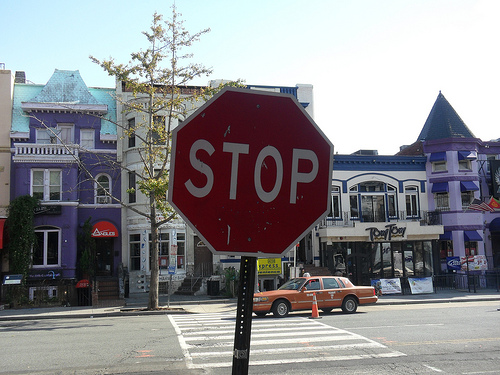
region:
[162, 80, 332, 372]
a red and white stop sign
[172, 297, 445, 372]
white lines forming a crosswalk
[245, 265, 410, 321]
orange taxi on street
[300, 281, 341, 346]
orange traffic cone on street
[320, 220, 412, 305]
store sign over first story of building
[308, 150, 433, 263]
white building with blue details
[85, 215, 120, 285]
red awning over entrance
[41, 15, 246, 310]
tree in front of buildings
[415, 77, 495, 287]
purple building with purple awnings over windows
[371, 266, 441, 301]
signs on the sidewalk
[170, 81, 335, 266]
A stop sign.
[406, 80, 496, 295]
The roof of purple building is shaped like a pyramid.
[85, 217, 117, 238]
A red business sign.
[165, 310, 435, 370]
A crosswalk.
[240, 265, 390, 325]
A traffic cone is next to a taxi.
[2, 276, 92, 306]
A metal fence.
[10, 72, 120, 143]
The roof is light blue.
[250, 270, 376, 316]
An orange taxi.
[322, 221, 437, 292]
The storefront of a business.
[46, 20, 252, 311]
A large tree with few leaves.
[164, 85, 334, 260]
red octagonal stop sign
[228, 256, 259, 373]
metal pole supporting stop sign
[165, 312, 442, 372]
painted crosswalk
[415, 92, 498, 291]
building with blue awnings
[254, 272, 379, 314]
orange taxicab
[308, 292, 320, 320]
orange safety cone in street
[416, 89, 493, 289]
building with conical roof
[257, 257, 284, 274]
yellow store awning that says "express"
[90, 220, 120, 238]
red store awning above door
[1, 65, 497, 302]
row of commercial establishments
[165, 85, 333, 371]
The red stop sign with white writing.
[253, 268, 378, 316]
The orange taxi cab.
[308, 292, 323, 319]
The orange and white construction cone.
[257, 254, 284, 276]
The yellow express sign.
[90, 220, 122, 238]
The red awning with white designs.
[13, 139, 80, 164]
The white top floor balcony.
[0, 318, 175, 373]
A grey road with shadows.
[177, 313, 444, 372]
The white road lines.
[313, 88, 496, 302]
The businesses in the area.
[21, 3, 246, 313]
The one tall tree.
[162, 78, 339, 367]
A RED AND WHITE STOP SIGN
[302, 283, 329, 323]
AN ORANGE TRAFFIC CONE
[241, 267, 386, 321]
AN ORANGE TAXI CAB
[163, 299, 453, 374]
WHITE CROSS WALK MARKINGS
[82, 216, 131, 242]
A RED AWNING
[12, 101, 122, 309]
A PURPLE AND WHITE BUILDING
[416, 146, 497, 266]
SIX WINDOWS WITH AWNINGS?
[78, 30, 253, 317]
A TREE ACROSS THE STREET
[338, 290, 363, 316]
A REAR CAR TIRE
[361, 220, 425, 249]
THE NAME OF AN ESTABLISHMENT